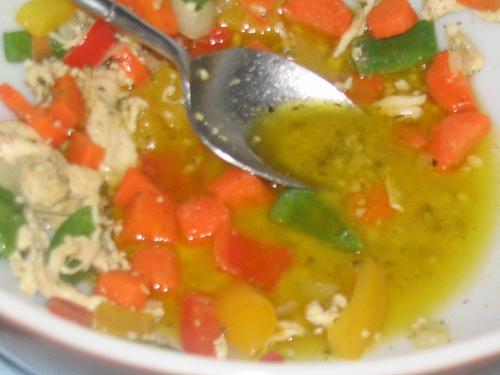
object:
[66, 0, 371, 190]
spoon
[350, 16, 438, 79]
peppers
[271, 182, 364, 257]
peppers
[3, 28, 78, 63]
peppers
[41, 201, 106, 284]
peppers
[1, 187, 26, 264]
peppers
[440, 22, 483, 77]
meat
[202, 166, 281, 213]
carrot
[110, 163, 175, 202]
carrot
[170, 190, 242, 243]
carrot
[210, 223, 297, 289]
carrot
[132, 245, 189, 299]
carrot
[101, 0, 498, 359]
broth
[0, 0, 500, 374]
bowl